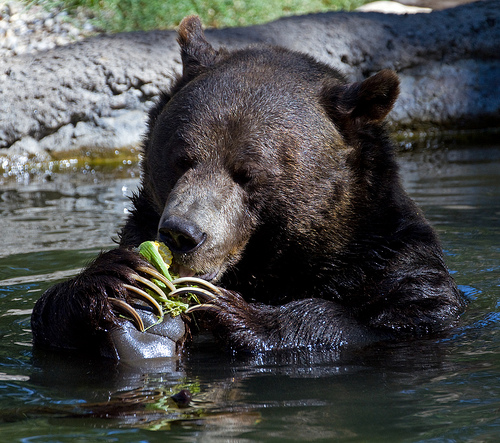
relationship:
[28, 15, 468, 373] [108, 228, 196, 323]
bear eating something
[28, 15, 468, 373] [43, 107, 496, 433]
bear in water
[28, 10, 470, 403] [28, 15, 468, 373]
fur on bear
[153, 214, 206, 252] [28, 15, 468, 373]
snout on bear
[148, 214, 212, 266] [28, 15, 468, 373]
snout on bear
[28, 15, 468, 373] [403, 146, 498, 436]
bear sitting in water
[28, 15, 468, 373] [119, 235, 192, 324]
bear eating food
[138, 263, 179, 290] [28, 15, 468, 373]
claw on bear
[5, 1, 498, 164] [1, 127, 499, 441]
ground next to water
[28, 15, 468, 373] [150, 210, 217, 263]
bear has nose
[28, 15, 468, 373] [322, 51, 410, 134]
bear has ear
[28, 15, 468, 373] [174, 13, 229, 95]
bear has ear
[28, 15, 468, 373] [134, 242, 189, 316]
bear holds thing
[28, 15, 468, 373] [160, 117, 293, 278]
bear has face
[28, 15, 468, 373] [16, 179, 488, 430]
bear in water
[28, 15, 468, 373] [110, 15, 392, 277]
bear has head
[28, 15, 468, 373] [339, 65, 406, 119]
bear has ear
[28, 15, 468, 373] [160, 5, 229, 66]
bear has ear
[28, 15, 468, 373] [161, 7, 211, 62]
bear has ear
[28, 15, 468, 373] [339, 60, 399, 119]
bear has ear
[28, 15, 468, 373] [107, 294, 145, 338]
bear has claw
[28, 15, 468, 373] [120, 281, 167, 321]
bear has claw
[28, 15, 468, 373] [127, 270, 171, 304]
bear has claw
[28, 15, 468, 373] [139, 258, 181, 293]
bear has claw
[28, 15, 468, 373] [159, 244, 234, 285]
bear has mouth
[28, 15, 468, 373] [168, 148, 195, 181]
bear has eye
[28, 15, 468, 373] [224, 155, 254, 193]
bear has eye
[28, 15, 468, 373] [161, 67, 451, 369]
bear has fur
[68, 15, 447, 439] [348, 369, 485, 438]
bear sitting in water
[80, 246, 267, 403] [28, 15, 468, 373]
paws of bear